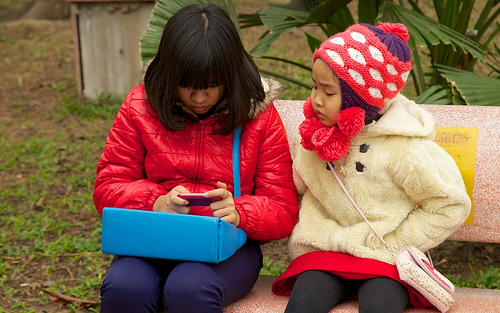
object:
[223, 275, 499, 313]
bench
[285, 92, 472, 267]
jacket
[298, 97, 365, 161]
tie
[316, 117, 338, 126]
chin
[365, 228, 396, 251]
pocket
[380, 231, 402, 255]
hand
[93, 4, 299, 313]
girl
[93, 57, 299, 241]
jacket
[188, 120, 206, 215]
zipper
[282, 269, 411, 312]
skirt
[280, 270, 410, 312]
leggings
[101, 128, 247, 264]
purse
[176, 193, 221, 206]
cellphone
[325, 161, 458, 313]
purse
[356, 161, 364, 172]
buttons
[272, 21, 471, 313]
child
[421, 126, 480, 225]
sign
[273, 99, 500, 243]
bench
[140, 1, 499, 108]
plant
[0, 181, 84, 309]
leaf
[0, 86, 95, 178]
ground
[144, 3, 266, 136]
hair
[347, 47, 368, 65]
dot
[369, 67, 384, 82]
dot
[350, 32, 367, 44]
dot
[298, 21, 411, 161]
hat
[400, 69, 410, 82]
dot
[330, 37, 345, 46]
dot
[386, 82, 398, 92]
dot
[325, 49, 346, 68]
dot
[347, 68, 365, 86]
dot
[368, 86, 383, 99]
polka dot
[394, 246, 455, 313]
bag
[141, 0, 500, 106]
leaves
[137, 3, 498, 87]
leaves